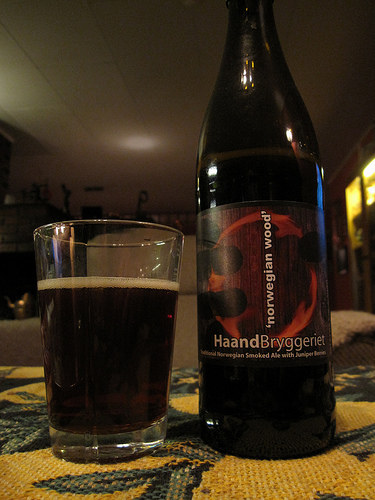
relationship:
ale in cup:
[30, 272, 182, 442] [31, 216, 183, 463]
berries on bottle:
[206, 218, 316, 337] [184, 2, 340, 464]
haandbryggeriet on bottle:
[209, 332, 328, 353] [184, 2, 340, 464]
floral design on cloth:
[0, 364, 370, 499] [0, 366, 375, 496]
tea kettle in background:
[3, 288, 40, 322] [2, 144, 372, 362]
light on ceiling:
[116, 132, 161, 151] [1, 4, 361, 192]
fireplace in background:
[0, 197, 51, 305] [2, 144, 372, 362]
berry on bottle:
[197, 239, 247, 329] [184, 2, 340, 464]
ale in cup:
[37, 274, 180, 435] [31, 216, 183, 463]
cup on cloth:
[31, 216, 183, 463] [0, 366, 375, 496]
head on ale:
[47, 272, 173, 290] [37, 274, 180, 435]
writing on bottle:
[205, 332, 329, 353] [184, 2, 340, 464]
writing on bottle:
[257, 209, 281, 328] [184, 2, 340, 464]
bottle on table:
[184, 2, 340, 464] [0, 364, 375, 500]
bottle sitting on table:
[184, 2, 340, 464] [0, 364, 375, 500]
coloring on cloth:
[23, 462, 216, 497] [0, 366, 375, 496]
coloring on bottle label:
[204, 205, 323, 342] [199, 200, 331, 360]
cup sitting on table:
[31, 216, 183, 463] [0, 364, 375, 500]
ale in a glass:
[37, 274, 180, 435] [18, 219, 193, 451]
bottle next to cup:
[184, 2, 340, 464] [31, 216, 183, 463]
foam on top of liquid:
[35, 274, 180, 293] [40, 286, 166, 423]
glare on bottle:
[193, 413, 221, 424] [184, 2, 340, 464]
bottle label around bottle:
[199, 200, 331, 360] [184, 2, 340, 464]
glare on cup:
[47, 222, 73, 237] [31, 216, 183, 463]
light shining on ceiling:
[116, 132, 169, 159] [0, 4, 195, 203]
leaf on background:
[24, 469, 152, 491] [1, 377, 358, 498]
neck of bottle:
[195, 1, 309, 48] [176, 22, 348, 459]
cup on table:
[31, 216, 183, 463] [0, 364, 375, 500]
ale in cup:
[37, 274, 180, 435] [25, 216, 184, 460]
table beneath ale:
[0, 364, 375, 500] [182, 2, 344, 463]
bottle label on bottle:
[199, 200, 331, 360] [184, 2, 340, 464]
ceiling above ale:
[1, 4, 361, 192] [182, 2, 344, 463]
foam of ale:
[35, 274, 180, 293] [36, 289, 175, 424]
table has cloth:
[4, 364, 355, 474] [27, 467, 361, 496]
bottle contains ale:
[184, 2, 340, 464] [211, 156, 304, 200]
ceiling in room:
[1, 4, 361, 192] [2, 5, 358, 492]